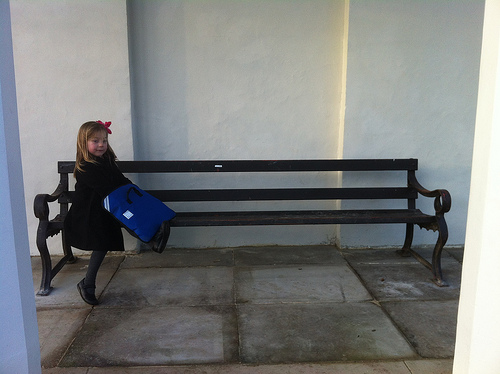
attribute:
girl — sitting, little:
[59, 120, 135, 305]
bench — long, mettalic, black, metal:
[32, 159, 451, 297]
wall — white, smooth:
[9, 1, 488, 256]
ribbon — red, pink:
[97, 118, 113, 134]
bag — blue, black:
[99, 180, 177, 253]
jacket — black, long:
[61, 157, 131, 253]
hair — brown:
[72, 120, 118, 175]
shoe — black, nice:
[76, 276, 99, 305]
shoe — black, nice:
[149, 221, 169, 254]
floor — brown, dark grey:
[28, 244, 464, 371]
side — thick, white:
[8, 0, 148, 255]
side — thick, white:
[336, 1, 486, 248]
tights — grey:
[83, 245, 106, 289]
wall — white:
[1, 1, 43, 372]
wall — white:
[451, 1, 498, 373]